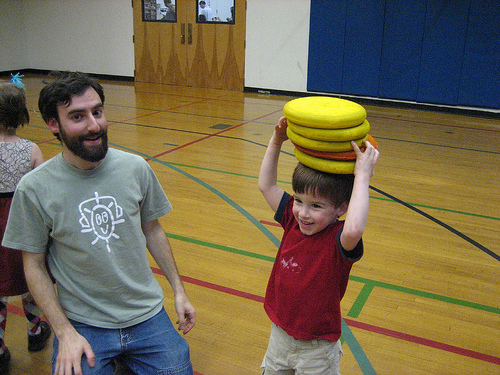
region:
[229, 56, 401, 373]
a boy with a pile of frisbees on his head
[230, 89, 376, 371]
a boy in red shirt with frisbees on his head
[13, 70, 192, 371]
a guy wearing jeans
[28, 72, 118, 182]
a guy with a beard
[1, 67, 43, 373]
a little girl behind the man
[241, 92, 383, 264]
a boy balancing the frisbee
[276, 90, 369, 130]
a yellow frisbee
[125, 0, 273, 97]
a double door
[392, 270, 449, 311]
a green line on the floor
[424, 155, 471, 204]
a floor made of wood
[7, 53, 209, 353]
this man looks happy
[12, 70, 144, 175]
the man has facial hair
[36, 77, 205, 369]
he is wearing a green shirt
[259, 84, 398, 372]
the little kid has a stack of flat discs on his head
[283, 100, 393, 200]
the majority of discs are yellow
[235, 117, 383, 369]
the kid is dressed in red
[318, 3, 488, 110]
blue pads are in the back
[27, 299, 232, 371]
the man is wearing blue jeans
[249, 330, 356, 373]
the boy is wearing white pants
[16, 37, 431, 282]
both the man & boy are smiling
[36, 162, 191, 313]
the man is wearing a gray t-shirt with an image on the front of it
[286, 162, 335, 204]
the boy has short brown hair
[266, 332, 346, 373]
the boy is wearing khaki colored pants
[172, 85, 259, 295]
the people are in a gymnasium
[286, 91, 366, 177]
the boy is balancing yellow and orange round disks on top of his head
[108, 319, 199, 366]
the man is wearing dark blue jeans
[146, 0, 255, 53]
there are people outside of the gym behind the door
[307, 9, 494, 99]
dark blue padded mats are on the wall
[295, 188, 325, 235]
the boy has a smile on his face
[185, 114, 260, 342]
on the floor there are different colors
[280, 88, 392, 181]
a few yellow discs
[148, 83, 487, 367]
a few colorful lines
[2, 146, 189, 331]
a grey and white shirt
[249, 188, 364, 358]
a kids red shirt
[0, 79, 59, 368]
a girl in a dress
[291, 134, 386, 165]
a bright orange disc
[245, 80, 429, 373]
a boy playing on a court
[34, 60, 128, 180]
a man wearing a goatee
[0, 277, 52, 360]
a pair of argyle tights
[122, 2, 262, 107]
a pair of wooden doors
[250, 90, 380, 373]
the little boy standing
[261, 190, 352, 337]
the red shirt on the little boy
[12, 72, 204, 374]
the man kneeling next to the little boy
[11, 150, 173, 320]
the shirt on the man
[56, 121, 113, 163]
the short beard on the man's face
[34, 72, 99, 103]
the dark hair on the man's head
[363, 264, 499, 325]
the green line on the ground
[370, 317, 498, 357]
the red line on the ground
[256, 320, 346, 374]
the light colored bottoms on the boy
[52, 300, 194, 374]
the man's denim bottoms